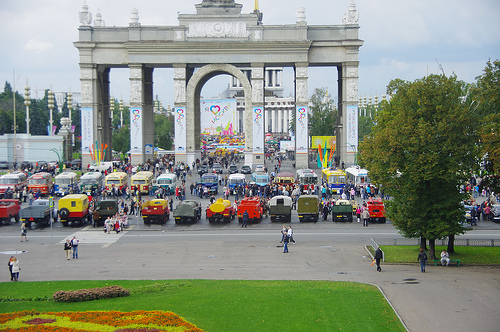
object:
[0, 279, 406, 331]
grass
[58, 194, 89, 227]
car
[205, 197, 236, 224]
car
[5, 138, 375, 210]
people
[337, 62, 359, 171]
column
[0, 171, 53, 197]
buses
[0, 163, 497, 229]
parking lot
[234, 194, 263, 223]
car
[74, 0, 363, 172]
monument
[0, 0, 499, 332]
city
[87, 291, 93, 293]
flower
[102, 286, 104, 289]
flower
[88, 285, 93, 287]
flower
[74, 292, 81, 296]
flower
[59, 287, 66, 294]
flower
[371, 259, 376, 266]
man bag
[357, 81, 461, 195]
leaves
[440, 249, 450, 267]
person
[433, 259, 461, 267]
bench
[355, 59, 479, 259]
tree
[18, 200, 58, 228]
bed truck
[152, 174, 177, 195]
bus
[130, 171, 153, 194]
bus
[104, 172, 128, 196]
bus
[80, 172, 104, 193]
bus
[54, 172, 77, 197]
bus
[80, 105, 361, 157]
banner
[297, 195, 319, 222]
vehicle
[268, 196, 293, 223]
vehicle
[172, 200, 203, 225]
vehicle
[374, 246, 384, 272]
person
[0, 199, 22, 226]
cars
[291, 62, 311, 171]
column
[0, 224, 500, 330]
ground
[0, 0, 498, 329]
park